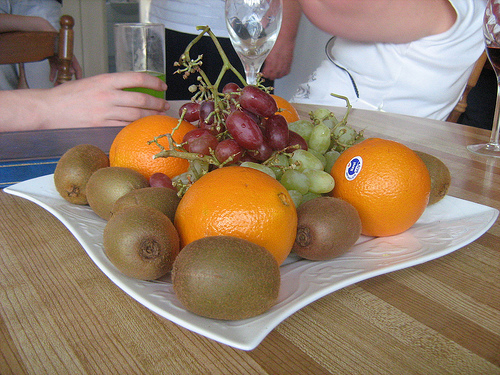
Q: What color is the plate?
A: White.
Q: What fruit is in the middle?
A: Grapes.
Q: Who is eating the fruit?
A: No one.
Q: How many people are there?
A: Two.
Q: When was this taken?
A: During the day.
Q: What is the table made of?
A: Wood.